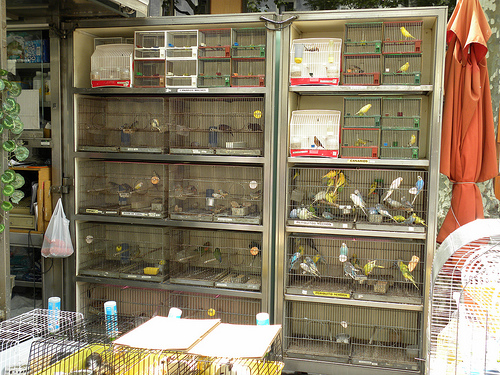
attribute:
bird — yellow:
[395, 22, 419, 44]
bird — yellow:
[395, 61, 419, 76]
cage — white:
[165, 28, 196, 61]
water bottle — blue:
[44, 291, 64, 332]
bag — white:
[39, 192, 76, 261]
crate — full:
[285, 166, 427, 238]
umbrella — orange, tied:
[438, 1, 499, 238]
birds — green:
[195, 238, 224, 262]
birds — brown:
[216, 121, 264, 139]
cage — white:
[292, 37, 341, 87]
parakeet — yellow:
[354, 101, 373, 121]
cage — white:
[166, 57, 200, 90]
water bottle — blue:
[103, 299, 123, 342]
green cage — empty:
[344, 22, 381, 55]